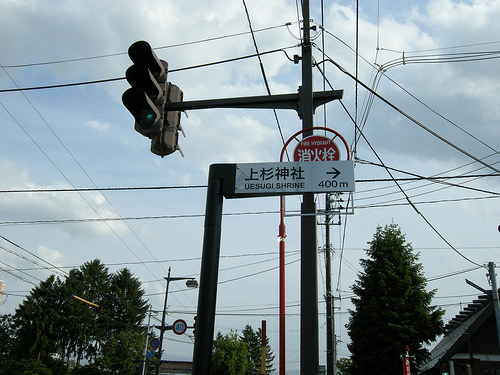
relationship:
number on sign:
[171, 315, 189, 339] [172, 319, 186, 337]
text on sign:
[248, 166, 300, 180] [213, 158, 365, 203]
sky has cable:
[22, 17, 487, 267] [0, 44, 300, 93]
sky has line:
[22, 17, 487, 267] [155, 31, 250, 48]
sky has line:
[22, 17, 487, 267] [257, 55, 269, 92]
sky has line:
[22, 17, 487, 267] [55, 184, 169, 191]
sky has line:
[22, 17, 487, 267] [386, 168, 425, 219]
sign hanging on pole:
[186, 146, 372, 205] [193, 178, 222, 373]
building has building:
[414, 288, 499, 373] [414, 288, 499, 374]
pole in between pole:
[298, 0, 321, 374] [322, 192, 346, 372]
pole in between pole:
[298, 0, 321, 374] [277, 197, 287, 372]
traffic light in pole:
[121, 40, 188, 159] [272, 61, 366, 373]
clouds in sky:
[5, 4, 115, 203] [2, 3, 498, 314]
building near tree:
[414, 288, 499, 374] [344, 222, 440, 373]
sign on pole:
[288, 137, 341, 162] [275, 181, 292, 373]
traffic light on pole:
[123, 41, 184, 156] [161, 7, 342, 373]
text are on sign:
[245, 166, 305, 180] [235, 160, 356, 192]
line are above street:
[341, 149, 500, 208] [0, 295, 497, 373]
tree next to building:
[349, 217, 457, 369] [412, 279, 489, 371]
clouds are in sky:
[27, 110, 141, 203] [5, 1, 499, 372]